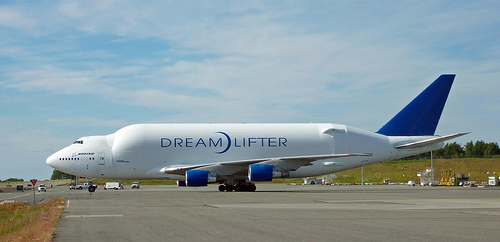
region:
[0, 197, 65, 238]
a section of green and brown grass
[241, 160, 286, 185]
a plane engine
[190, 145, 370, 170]
the wing of a plane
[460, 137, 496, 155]
tall green trees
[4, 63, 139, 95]
a white cloud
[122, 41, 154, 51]
part of a blue sky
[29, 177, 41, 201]
a red sign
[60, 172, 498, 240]
a large concrete runway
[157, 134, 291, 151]
the name of the airline company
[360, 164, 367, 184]
a tall gray pole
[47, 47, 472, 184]
white plane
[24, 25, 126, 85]
white clouds in blue sky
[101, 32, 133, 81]
white clouds in blue sky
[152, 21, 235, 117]
white clouds in blue sky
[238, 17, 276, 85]
white clouds in blue sky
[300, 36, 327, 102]
white clouds in blue sky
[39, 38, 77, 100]
white clouds in blue sky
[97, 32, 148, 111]
white clouds in blue sky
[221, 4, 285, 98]
white clouds in blue sky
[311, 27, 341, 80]
white clouds in blue sky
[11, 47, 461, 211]
airplane on the runway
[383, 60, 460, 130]
tail of the airplane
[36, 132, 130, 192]
nose of the airplane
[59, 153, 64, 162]
window of the airplane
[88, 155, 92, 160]
window of the airplane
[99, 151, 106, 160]
window of the airplane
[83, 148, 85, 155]
window of the airplane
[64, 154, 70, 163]
window of the airplane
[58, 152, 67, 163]
window of the airplane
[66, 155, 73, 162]
window of the airplane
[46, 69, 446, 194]
blue and white plane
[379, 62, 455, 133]
plane has blue tail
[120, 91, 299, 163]
blue company name on plane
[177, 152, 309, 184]
blue engines on plane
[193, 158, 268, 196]
black wheels on plane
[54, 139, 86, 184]
white nose on plane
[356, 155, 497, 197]
green grass on hill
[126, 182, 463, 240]
grey road on tarmac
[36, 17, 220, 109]
sky is blue and cloudy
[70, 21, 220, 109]
few thin white clouds in sky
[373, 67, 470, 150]
plane's tail is blue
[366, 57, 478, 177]
plane's tail is blue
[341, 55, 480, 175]
plane's tail is blue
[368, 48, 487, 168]
plane's tail is blue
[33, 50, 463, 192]
the plane is white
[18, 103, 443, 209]
the plane is white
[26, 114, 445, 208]
the plane is white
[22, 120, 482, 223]
the plane is white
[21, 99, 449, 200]
the plane is white